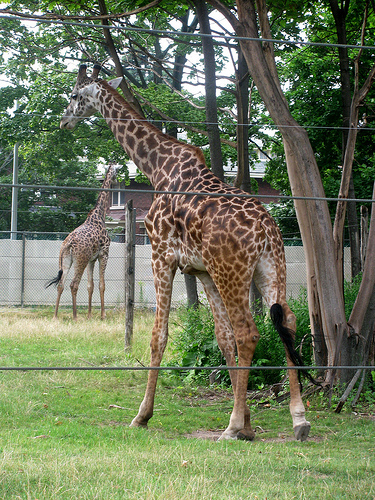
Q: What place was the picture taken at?
A: It was taken at the field.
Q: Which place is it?
A: It is a field.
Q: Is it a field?
A: Yes, it is a field.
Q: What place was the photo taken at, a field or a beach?
A: It was taken at a field.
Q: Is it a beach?
A: No, it is a field.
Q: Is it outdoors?
A: Yes, it is outdoors.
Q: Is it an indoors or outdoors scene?
A: It is outdoors.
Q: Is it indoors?
A: No, it is outdoors.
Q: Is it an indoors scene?
A: No, it is outdoors.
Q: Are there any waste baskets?
A: No, there are no waste baskets.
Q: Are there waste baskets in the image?
A: No, there are no waste baskets.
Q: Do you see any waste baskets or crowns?
A: No, there are no waste baskets or crowns.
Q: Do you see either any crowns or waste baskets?
A: No, there are no waste baskets or crowns.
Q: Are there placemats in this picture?
A: No, there are no placemats.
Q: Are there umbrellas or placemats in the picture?
A: No, there are no placemats or umbrellas.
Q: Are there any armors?
A: No, there are no armors.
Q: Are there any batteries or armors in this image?
A: No, there are no armors or batteries.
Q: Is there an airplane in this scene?
A: No, there are no airplanes.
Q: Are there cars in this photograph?
A: No, there are no cars.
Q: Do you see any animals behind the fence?
A: Yes, there is an animal behind the fence.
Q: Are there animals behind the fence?
A: Yes, there is an animal behind the fence.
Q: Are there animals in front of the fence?
A: No, the animal is behind the fence.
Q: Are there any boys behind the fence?
A: No, there is an animal behind the fence.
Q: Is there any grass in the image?
A: Yes, there is grass.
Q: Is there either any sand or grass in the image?
A: Yes, there is grass.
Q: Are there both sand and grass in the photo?
A: No, there is grass but no sand.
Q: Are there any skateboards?
A: No, there are no skateboards.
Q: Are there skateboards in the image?
A: No, there are no skateboards.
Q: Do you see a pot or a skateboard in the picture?
A: No, there are no skateboards or pots.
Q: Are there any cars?
A: No, there are no cars.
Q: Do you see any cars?
A: No, there are no cars.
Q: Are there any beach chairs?
A: No, there are no beach chairs.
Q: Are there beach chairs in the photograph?
A: No, there are no beach chairs.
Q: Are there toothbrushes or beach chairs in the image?
A: No, there are no beach chairs or toothbrushes.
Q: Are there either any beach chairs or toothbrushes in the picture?
A: No, there are no beach chairs or toothbrushes.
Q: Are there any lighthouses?
A: No, there are no lighthouses.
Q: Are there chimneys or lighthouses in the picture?
A: No, there are no lighthouses or chimneys.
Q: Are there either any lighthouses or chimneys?
A: No, there are no lighthouses or chimneys.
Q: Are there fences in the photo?
A: Yes, there is a fence.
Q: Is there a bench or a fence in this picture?
A: Yes, there is a fence.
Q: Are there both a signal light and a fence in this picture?
A: No, there is a fence but no traffic lights.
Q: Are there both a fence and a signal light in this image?
A: No, there is a fence but no traffic lights.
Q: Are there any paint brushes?
A: No, there are no paint brushes.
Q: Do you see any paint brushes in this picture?
A: No, there are no paint brushes.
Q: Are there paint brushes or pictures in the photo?
A: No, there are no paint brushes or pictures.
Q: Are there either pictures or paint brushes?
A: No, there are no paint brushes or pictures.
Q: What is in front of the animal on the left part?
A: The fence is in front of the animal.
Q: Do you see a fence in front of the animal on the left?
A: Yes, there is a fence in front of the animal.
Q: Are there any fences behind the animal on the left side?
A: No, the fence is in front of the animal.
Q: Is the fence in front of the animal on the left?
A: Yes, the fence is in front of the animal.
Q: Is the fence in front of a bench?
A: No, the fence is in front of the animal.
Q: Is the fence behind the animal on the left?
A: No, the fence is in front of the animal.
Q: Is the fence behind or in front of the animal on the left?
A: The fence is in front of the animal.